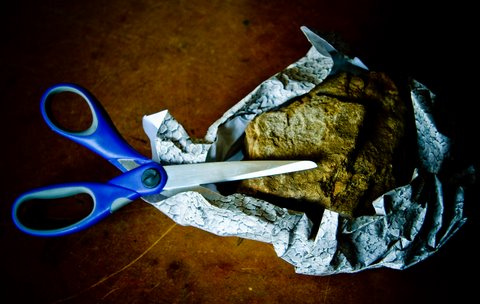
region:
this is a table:
[137, 241, 202, 280]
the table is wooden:
[137, 243, 189, 279]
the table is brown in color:
[106, 237, 138, 271]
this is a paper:
[205, 202, 231, 221]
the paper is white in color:
[207, 196, 257, 237]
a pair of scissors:
[13, 86, 316, 253]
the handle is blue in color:
[99, 132, 120, 151]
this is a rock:
[250, 73, 422, 201]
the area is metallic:
[192, 163, 228, 176]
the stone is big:
[288, 117, 373, 173]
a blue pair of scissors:
[5, 76, 321, 259]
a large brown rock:
[228, 49, 422, 219]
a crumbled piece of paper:
[134, 24, 470, 278]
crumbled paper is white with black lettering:
[140, 19, 475, 292]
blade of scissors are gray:
[157, 146, 320, 194]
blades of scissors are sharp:
[151, 142, 328, 198]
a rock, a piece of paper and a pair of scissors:
[13, 21, 478, 276]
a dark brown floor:
[3, 0, 478, 298]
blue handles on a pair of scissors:
[8, 78, 169, 244]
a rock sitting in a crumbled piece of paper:
[128, 15, 479, 280]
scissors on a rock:
[56, 33, 418, 252]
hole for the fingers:
[12, 177, 109, 244]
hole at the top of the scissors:
[39, 80, 104, 141]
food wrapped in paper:
[137, 35, 471, 281]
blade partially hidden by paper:
[160, 184, 263, 227]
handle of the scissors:
[1, 66, 179, 238]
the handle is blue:
[8, 64, 158, 257]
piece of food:
[223, 54, 444, 226]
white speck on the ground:
[245, 282, 257, 293]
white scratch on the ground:
[88, 218, 177, 295]